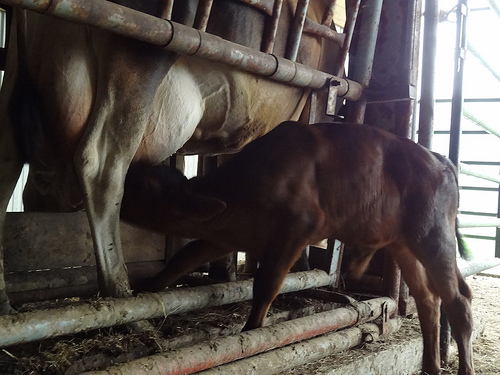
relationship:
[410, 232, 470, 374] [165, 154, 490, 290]
leg of a cow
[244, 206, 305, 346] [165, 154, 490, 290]
front leg of a cow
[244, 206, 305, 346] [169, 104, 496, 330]
front leg of a calf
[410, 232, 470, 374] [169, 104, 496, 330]
leg of a calf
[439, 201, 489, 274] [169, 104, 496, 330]
tail of a calf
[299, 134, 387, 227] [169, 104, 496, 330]
brown colored calf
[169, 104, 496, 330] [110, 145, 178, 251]
calf drinking milk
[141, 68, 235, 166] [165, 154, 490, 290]
udder of a cow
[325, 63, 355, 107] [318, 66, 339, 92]
nut and a bolt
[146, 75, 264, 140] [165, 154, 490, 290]
veins on cow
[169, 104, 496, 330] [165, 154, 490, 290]
small brown cow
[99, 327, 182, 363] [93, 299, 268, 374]
hay on ground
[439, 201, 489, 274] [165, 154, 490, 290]
tail of cow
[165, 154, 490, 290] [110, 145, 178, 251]
cow full of milk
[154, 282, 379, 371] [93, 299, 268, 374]
pipes on ground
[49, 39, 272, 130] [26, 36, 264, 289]
cow tan and white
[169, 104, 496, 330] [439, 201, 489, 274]
calf has short tail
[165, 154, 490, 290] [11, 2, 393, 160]
cow in enclosure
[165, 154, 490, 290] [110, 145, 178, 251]
cow drinking milk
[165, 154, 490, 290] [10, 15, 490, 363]
cow in a barn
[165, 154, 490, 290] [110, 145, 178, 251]
cow drinking from mom milk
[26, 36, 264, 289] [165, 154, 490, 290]
white mom cow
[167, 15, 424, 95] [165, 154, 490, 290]
cage around cow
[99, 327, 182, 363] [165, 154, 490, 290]
hay below cow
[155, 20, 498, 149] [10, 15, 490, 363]
metal fence outside barn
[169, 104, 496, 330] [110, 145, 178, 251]
baby cow drinking milk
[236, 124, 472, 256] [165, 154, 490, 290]
muscles on cow